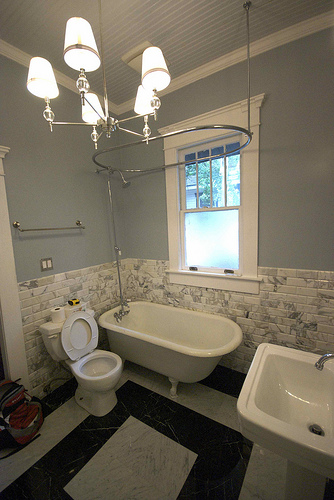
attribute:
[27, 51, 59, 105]
light — hanging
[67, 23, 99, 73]
light — hanging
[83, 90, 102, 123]
light — hanging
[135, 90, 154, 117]
light — hanging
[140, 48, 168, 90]
light — hanging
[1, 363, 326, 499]
floor — gray, black, white, square, tile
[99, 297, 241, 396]
bathtub — white, old fashioned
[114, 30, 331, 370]
wall — green, tiled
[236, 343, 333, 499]
sink — white, free-standing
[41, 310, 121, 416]
toilet — white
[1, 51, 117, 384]
wall — green, tiled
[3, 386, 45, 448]
backpack — red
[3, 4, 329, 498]
bathroom — large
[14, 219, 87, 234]
towel rack — silver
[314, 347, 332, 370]
faucet — silver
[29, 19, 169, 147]
chandelier — hanging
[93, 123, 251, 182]
curtain holder — metal, empty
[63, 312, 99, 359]
toilet seat — up